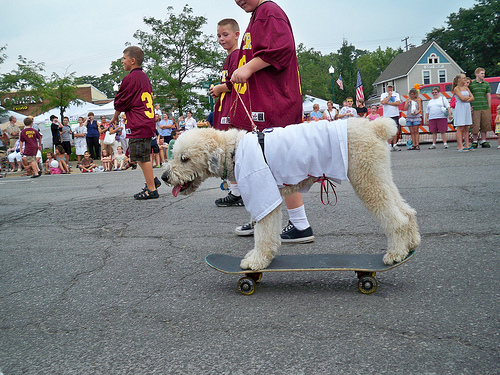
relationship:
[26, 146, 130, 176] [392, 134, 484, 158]
child sits along curb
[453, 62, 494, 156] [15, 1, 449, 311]
couple watching parade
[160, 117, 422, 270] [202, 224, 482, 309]
dog riding skateboard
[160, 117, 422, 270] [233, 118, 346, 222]
dog wearing t-shirt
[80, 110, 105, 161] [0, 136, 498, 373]
person standing along road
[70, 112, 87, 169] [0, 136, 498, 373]
person standing along road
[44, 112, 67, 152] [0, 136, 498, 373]
person standing along road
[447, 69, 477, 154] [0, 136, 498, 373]
person standing along road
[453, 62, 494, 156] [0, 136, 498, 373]
couple standing along road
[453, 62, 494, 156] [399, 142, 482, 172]
couple standing along roadside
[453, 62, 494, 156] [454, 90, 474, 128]
couple wearing sundress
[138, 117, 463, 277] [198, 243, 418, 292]
dog riding skateboard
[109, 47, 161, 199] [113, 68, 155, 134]
kid wearing jersey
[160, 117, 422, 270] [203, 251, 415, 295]
dog on skateboard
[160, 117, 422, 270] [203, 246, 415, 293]
dog on skateboard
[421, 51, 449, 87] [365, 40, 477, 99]
windows on top of house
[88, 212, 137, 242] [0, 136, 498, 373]
crack in road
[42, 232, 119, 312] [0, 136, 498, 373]
crack in road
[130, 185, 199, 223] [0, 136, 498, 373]
crack in road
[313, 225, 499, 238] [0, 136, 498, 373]
crack in road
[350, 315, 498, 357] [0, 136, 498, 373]
crack in road